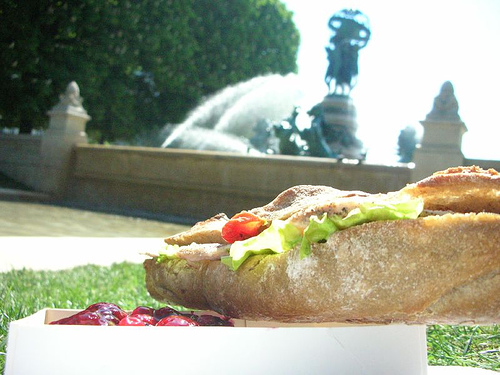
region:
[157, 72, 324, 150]
water spraying in fountain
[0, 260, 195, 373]
green grass behind sandwich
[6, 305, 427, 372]
white cardboard box under sandwich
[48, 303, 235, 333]
red cranberry sauce in box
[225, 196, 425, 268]
green leaf lettuce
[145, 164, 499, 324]
crusty sandwich balanced on box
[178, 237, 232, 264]
lunch meat next to lettuce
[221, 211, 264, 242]
tomato on top of lettuce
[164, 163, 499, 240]
crusty bread on lettuce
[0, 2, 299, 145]
green tree behind fountain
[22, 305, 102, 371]
the box is white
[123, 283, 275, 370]
the box is white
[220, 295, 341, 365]
the box is white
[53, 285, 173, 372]
the box is white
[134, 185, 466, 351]
the bread is brown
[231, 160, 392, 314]
the bread is brown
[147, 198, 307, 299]
the bread is brown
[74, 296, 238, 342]
the topping is red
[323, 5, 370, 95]
Statue in middle of water fountain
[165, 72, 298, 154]
Water spraying in the air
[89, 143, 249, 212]
Concrete retaining wall around water fountain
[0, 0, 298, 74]
Large tree with green leaves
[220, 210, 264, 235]
Piece of tomato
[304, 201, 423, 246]
Green lettuce leaf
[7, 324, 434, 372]
Square white food box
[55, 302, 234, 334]
Red food inside white box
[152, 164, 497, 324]
Large sub sandwich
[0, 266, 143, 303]
Stretch of green grass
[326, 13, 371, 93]
A statue by the tree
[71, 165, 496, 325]
Food by the grass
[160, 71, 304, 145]
Water by the statue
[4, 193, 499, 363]
Grass below the food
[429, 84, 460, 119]
A statue on a pillar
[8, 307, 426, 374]
The box that holds the food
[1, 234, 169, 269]
A path between the grass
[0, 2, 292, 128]
A green tree near the water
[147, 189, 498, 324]
A sandwich by the grass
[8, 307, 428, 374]
The box is open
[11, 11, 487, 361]
sandwich in front of ornate park fountain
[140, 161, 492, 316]
lettuce, tomato and meat in crusty long bread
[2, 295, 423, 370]
gooey red berries over edge of long white box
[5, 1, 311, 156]
dense green tree in back of curved water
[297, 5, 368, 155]
muted figures on top of tall pedestal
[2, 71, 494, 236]
beige wall with columns topped with ovals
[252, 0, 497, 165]
bright sky behind statue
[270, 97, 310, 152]
curved and extended figures near pedestal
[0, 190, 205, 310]
white reflection between grass and stone floor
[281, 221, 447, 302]
flour dusted over side of bread